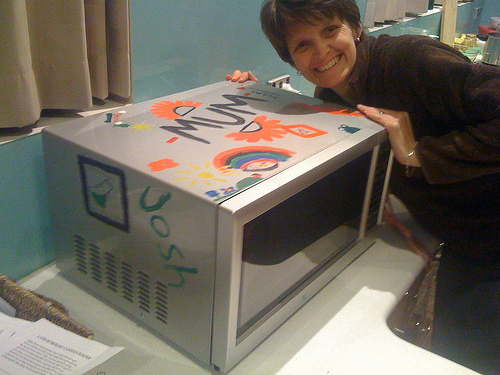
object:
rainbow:
[212, 145, 297, 173]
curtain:
[0, 0, 150, 127]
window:
[0, 0, 148, 135]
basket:
[0, 269, 94, 374]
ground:
[419, 156, 440, 178]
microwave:
[38, 78, 391, 373]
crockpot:
[482, 34, 500, 63]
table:
[21, 273, 440, 368]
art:
[151, 94, 270, 144]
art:
[138, 185, 196, 288]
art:
[78, 155, 130, 233]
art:
[211, 145, 296, 174]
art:
[151, 100, 203, 121]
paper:
[1, 317, 124, 374]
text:
[20, 344, 67, 367]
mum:
[160, 92, 268, 143]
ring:
[379, 112, 384, 116]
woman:
[255, 0, 500, 374]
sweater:
[417, 38, 492, 188]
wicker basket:
[0, 272, 98, 340]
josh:
[138, 186, 199, 287]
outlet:
[268, 74, 293, 89]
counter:
[0, 191, 448, 375]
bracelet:
[405, 144, 416, 177]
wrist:
[394, 131, 432, 172]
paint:
[137, 185, 171, 212]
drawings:
[143, 86, 367, 195]